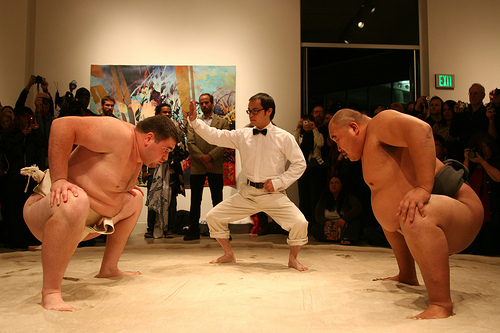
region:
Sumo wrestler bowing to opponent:
[308, 101, 493, 313]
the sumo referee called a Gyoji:
[183, 76, 315, 272]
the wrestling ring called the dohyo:
[0, 230, 496, 330]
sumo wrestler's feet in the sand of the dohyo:
[350, 256, 463, 323]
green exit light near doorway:
[430, 57, 457, 93]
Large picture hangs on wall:
[82, 52, 238, 189]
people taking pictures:
[12, 68, 95, 124]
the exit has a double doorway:
[287, 0, 433, 125]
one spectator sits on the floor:
[300, 161, 362, 257]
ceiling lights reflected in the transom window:
[286, 0, 451, 60]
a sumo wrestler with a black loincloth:
[321, 98, 486, 328]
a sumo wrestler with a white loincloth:
[17, 109, 186, 315]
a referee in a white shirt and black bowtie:
[208, 86, 314, 268]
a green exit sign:
[432, 72, 458, 89]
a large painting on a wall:
[78, 56, 244, 189]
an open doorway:
[291, 2, 436, 241]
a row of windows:
[303, 70, 416, 120]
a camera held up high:
[14, 69, 58, 91]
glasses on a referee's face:
[242, 106, 269, 117]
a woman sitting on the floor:
[308, 174, 365, 246]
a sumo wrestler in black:
[356, 82, 498, 308]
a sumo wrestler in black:
[316, 92, 366, 245]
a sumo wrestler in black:
[337, 107, 388, 292]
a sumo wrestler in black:
[347, 135, 409, 276]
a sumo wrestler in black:
[384, 75, 439, 278]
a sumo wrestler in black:
[422, 92, 443, 263]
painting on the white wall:
[91, 67, 236, 177]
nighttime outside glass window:
[302, 2, 429, 208]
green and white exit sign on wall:
[437, 73, 454, 87]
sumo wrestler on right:
[332, 103, 466, 302]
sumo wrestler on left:
[16, 100, 179, 280]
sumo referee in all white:
[187, 93, 319, 256]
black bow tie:
[251, 126, 266, 134]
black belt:
[244, 178, 264, 186]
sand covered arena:
[5, 247, 497, 330]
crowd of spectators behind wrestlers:
[5, 74, 490, 236]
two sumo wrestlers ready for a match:
[13, 116, 488, 326]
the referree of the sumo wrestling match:
[184, 90, 319, 281]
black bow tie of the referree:
[246, 124, 272, 146]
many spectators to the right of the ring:
[305, 76, 492, 146]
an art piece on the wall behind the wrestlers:
[78, 56, 237, 156]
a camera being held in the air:
[8, 65, 53, 115]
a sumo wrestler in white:
[23, 105, 168, 287]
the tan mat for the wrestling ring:
[146, 264, 359, 329]